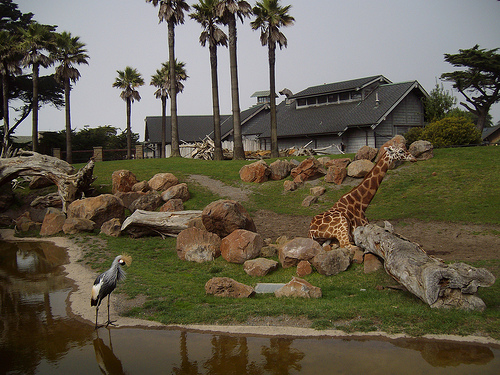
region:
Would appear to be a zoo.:
[6, 2, 492, 367]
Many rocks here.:
[110, 172, 311, 254]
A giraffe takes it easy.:
[296, 137, 423, 268]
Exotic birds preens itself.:
[62, 244, 139, 336]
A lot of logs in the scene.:
[343, 217, 494, 324]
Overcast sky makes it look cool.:
[23, 2, 279, 84]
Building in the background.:
[133, 75, 432, 150]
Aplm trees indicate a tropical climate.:
[0, 0, 96, 102]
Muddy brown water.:
[0, 234, 89, 373]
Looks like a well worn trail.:
[171, 162, 306, 237]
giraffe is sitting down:
[309, 135, 418, 269]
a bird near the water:
[84, 244, 129, 331]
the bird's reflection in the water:
[85, 331, 127, 373]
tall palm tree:
[104, 60, 146, 160]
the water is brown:
[2, 236, 495, 373]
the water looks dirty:
[2, 235, 495, 372]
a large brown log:
[347, 222, 494, 320]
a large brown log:
[2, 148, 99, 213]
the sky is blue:
[7, 0, 494, 132]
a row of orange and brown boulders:
[228, 134, 435, 191]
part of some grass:
[323, 248, 388, 295]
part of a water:
[213, 329, 247, 370]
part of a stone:
[216, 273, 241, 291]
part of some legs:
[87, 310, 104, 322]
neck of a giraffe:
[347, 154, 392, 200]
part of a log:
[414, 264, 456, 317]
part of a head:
[111, 247, 145, 277]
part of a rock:
[215, 201, 257, 283]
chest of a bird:
[86, 263, 111, 310]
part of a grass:
[181, 288, 230, 328]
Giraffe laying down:
[306, 135, 421, 260]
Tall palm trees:
[106, 2, 292, 158]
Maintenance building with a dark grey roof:
[144, 72, 449, 167]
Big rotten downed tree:
[1, 143, 111, 220]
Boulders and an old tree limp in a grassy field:
[102, 164, 308, 269]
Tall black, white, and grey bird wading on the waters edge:
[79, 244, 143, 342]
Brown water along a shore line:
[8, 319, 497, 374]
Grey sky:
[303, 2, 459, 74]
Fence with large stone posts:
[46, 137, 161, 162]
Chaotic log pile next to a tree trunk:
[178, 131, 230, 163]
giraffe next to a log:
[300, 136, 435, 250]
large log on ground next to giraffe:
[347, 213, 494, 337]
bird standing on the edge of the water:
[85, 254, 155, 331]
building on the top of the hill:
[137, 66, 438, 164]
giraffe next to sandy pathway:
[303, 131, 419, 273]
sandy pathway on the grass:
[184, 154, 494, 266]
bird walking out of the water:
[78, 251, 141, 338]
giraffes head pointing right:
[375, 142, 425, 172]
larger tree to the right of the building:
[427, 32, 494, 146]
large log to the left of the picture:
[4, 144, 110, 211]